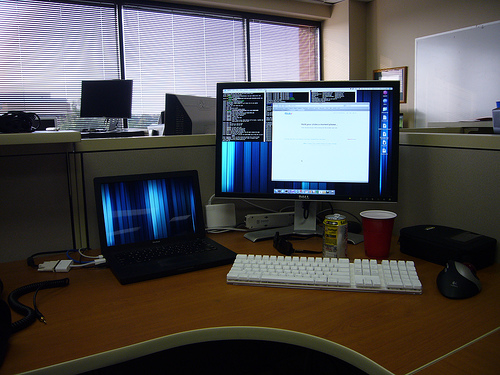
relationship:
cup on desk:
[361, 208, 398, 260] [2, 216, 500, 370]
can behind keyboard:
[324, 212, 349, 256] [220, 252, 423, 297]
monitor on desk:
[213, 78, 404, 202] [2, 216, 500, 370]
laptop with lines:
[92, 165, 236, 297] [101, 181, 194, 237]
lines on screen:
[101, 181, 194, 237] [92, 167, 206, 245]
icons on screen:
[379, 90, 393, 165] [223, 83, 394, 191]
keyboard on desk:
[220, 252, 423, 297] [2, 216, 500, 370]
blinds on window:
[1, 0, 321, 129] [3, 19, 327, 124]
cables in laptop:
[26, 245, 106, 268] [92, 165, 236, 297]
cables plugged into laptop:
[26, 245, 106, 268] [92, 165, 236, 297]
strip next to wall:
[242, 211, 298, 231] [7, 138, 500, 252]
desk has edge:
[2, 216, 500, 370] [44, 324, 393, 374]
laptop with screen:
[92, 165, 236, 297] [92, 167, 206, 245]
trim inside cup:
[359, 209, 398, 219] [361, 208, 398, 260]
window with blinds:
[3, 19, 327, 124] [1, 0, 321, 129]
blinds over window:
[1, 0, 321, 129] [3, 19, 327, 124]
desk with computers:
[2, 216, 500, 370] [92, 78, 422, 296]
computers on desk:
[92, 78, 422, 296] [2, 216, 500, 370]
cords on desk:
[3, 274, 73, 354] [2, 216, 500, 370]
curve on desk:
[26, 323, 397, 373] [2, 216, 500, 370]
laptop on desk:
[92, 165, 236, 297] [2, 216, 500, 370]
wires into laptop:
[24, 235, 107, 276] [92, 165, 236, 297]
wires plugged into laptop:
[24, 235, 107, 276] [92, 165, 236, 297]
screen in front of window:
[82, 78, 132, 122] [3, 19, 327, 124]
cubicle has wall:
[1, 127, 499, 369] [7, 138, 500, 252]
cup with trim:
[361, 208, 398, 260] [359, 208, 398, 220]